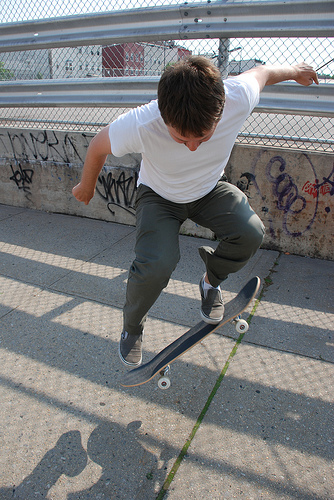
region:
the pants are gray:
[113, 191, 252, 342]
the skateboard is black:
[62, 263, 263, 393]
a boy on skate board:
[72, 56, 320, 390]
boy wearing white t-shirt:
[107, 72, 261, 203]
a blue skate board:
[116, 276, 261, 390]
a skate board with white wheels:
[157, 319, 250, 390]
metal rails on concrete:
[1, 3, 333, 117]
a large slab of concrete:
[1, 125, 333, 260]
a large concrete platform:
[1, 203, 333, 499]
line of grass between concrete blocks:
[156, 249, 284, 499]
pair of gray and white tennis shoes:
[116, 270, 224, 367]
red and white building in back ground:
[0, 37, 193, 79]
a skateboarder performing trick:
[70, 62, 320, 389]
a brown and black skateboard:
[120, 274, 261, 390]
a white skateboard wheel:
[156, 375, 169, 390]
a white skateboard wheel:
[234, 318, 248, 333]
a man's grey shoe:
[199, 271, 224, 323]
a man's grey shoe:
[118, 328, 142, 366]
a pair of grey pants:
[122, 181, 264, 334]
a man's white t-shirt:
[107, 74, 258, 202]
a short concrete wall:
[0, 126, 333, 259]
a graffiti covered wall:
[0, 127, 333, 258]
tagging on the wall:
[263, 154, 330, 236]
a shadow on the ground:
[19, 421, 163, 493]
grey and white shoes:
[116, 326, 144, 364]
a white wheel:
[233, 319, 248, 330]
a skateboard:
[148, 347, 181, 371]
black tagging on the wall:
[7, 127, 66, 160]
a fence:
[275, 117, 316, 139]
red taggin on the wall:
[300, 179, 330, 199]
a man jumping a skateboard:
[39, 60, 332, 392]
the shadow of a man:
[1, 420, 179, 498]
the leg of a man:
[119, 186, 181, 334]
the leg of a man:
[190, 171, 267, 282]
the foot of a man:
[113, 314, 147, 369]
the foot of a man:
[194, 266, 228, 325]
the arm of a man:
[57, 111, 137, 204]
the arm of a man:
[237, 49, 321, 109]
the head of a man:
[151, 46, 230, 157]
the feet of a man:
[102, 266, 229, 364]